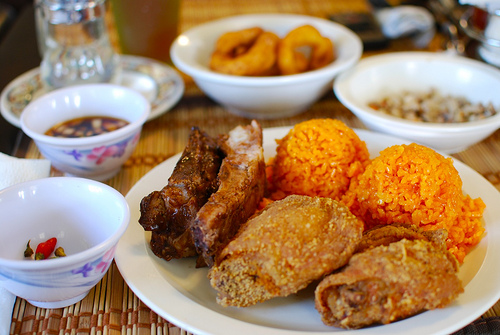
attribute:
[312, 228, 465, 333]
egg roll — fried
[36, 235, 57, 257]
red pepper — small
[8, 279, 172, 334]
placemat — wicker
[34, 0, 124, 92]
grinder — glass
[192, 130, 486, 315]
plate — white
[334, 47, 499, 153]
bowl — white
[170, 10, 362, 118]
bowl — white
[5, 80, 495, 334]
placemat — bamboo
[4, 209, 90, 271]
peppers — small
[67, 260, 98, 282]
flower — pink, purple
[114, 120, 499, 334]
plate — white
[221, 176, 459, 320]
chicken — fried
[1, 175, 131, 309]
bowl — white, porcelain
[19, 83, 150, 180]
bowl — white, small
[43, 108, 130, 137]
dark sauce — brown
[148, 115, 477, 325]
food — southern